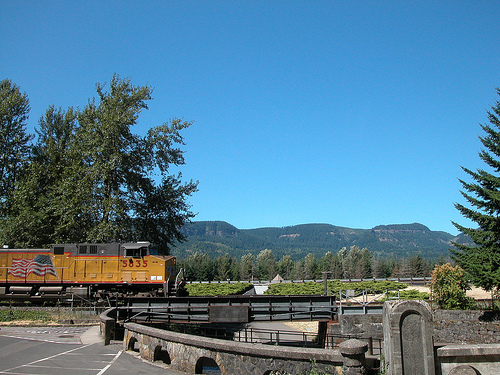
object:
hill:
[176, 219, 479, 262]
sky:
[194, 33, 352, 127]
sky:
[413, 39, 479, 97]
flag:
[7, 254, 59, 279]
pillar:
[380, 300, 437, 375]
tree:
[428, 96, 500, 316]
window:
[124, 244, 146, 259]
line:
[123, 319, 378, 361]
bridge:
[132, 294, 339, 325]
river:
[190, 351, 222, 373]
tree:
[0, 76, 203, 248]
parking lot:
[0, 325, 123, 374]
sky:
[211, 159, 453, 220]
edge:
[123, 319, 333, 361]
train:
[0, 240, 187, 307]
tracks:
[0, 295, 336, 302]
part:
[325, 67, 384, 142]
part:
[286, 223, 350, 282]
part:
[160, 115, 204, 253]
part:
[121, 241, 151, 262]